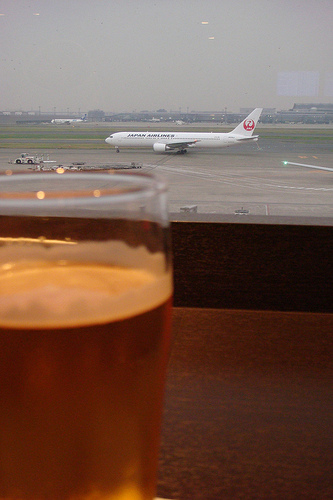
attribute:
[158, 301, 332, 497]
table — wood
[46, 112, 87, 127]
plane — white, furthest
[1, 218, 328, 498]
table — wooden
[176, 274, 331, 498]
table — brown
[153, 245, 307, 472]
table — brown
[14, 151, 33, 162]
car — small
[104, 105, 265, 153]
airline — japan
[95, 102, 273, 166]
plane — closest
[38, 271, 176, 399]
beer — brown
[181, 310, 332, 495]
table — wooden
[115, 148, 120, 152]
wheels — black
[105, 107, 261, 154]
plane — closest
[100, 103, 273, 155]
airplane — blue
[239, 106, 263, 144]
logo — red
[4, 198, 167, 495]
beer — foamy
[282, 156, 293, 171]
light — green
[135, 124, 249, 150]
airplane — japanese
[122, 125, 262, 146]
plane — closest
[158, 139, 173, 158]
engine — white, silver